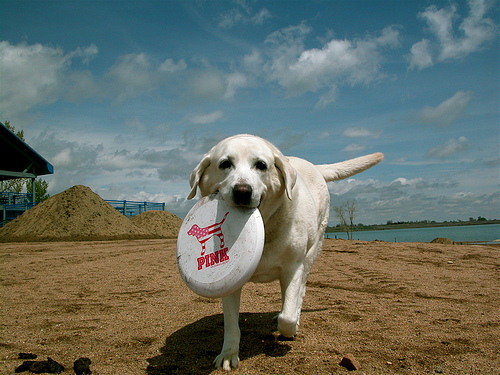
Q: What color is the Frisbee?
A: Red and white.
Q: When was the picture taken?
A: Daytime.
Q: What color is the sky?
A: Blue.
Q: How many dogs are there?
A: One.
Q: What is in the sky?
A: Clouds.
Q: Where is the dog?
A: On the beach.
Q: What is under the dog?
A: Sand.